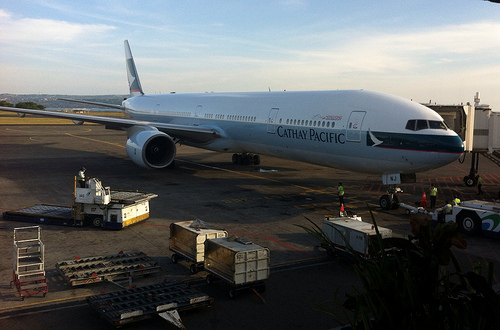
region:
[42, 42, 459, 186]
plane parked on tarmac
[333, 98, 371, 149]
door on side of plane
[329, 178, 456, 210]
airport workers on tarmac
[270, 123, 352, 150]
name of airline on plane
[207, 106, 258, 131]
windows on side of plane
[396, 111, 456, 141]
windshield on plane cockpit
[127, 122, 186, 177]
jet engine on wing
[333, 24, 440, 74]
thin white cloud in sky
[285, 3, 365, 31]
blue of daytime sky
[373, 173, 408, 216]
wheels on plane landing gear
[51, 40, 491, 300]
the plane is white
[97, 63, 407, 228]
the plane is white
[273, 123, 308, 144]
the word cathay on plane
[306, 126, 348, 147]
the word pacific on plane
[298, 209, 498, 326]
a tree in lot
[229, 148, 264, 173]
wheels on the plane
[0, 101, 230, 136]
a wing on plane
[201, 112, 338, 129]
windows on plane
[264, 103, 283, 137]
side door on plane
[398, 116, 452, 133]
windshield of the plane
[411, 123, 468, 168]
needlenose front of plane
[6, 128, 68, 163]
pavement is flat and grey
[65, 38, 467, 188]
The name of the plane is Cathay Pacific.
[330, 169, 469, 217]
The people are working on the plane.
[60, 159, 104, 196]
The man is waiting for the plane.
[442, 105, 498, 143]
The jet way is extended.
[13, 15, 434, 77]
The clouds are wispy.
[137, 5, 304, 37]
The sky color is light blue.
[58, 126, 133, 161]
The color the line is yellow.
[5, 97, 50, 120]
The color the tree is green.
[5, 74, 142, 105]
Hills are in the background.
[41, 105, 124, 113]
Water is slightly visible in the background.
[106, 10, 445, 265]
large plane on tarmac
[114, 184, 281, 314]
crates filled on top of tarmac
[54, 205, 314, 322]
luggage trailers attached to each other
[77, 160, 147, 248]
vehicle on tarmac by plane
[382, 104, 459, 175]
front end of plane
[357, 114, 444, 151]
front window of plane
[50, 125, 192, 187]
large engine of plane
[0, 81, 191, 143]
long wing on side of plane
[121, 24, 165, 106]
tail wing on end of plane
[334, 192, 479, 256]
workers below plane body